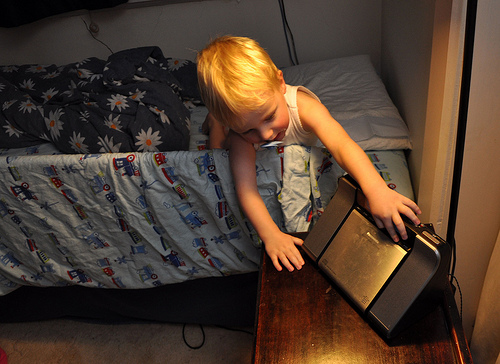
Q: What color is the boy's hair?
A: Blonde.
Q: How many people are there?
A: 1.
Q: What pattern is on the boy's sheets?
A: Trains.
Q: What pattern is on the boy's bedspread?
A: Flowers.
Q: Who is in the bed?
A: Boy.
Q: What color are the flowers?
A: White.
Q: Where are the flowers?
A: On the bedspread.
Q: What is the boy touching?
A: Radio.